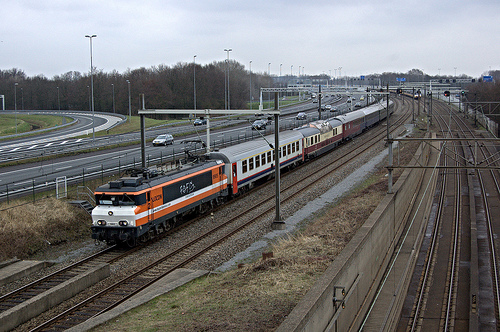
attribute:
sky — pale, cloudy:
[0, 1, 499, 80]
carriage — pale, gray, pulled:
[192, 124, 309, 203]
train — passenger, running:
[90, 99, 390, 246]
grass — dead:
[114, 171, 384, 331]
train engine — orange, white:
[89, 154, 230, 244]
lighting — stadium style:
[84, 26, 101, 134]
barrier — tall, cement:
[277, 126, 434, 330]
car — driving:
[147, 130, 177, 148]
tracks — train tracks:
[387, 162, 499, 253]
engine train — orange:
[91, 156, 228, 248]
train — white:
[102, 157, 261, 229]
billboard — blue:
[394, 75, 407, 81]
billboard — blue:
[480, 74, 492, 82]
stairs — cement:
[67, 196, 92, 221]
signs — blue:
[394, 71, 409, 84]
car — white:
[148, 128, 180, 150]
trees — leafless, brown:
[3, 60, 289, 116]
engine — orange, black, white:
[87, 151, 229, 250]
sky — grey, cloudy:
[1, 3, 496, 87]